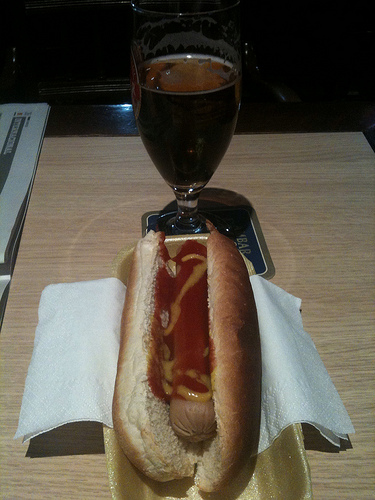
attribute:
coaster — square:
[135, 202, 274, 285]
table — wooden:
[276, 132, 363, 286]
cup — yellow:
[99, 245, 322, 498]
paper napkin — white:
[251, 275, 338, 441]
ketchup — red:
[144, 236, 219, 405]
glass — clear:
[123, 33, 206, 101]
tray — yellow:
[102, 234, 313, 498]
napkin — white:
[38, 290, 88, 425]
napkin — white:
[56, 274, 339, 432]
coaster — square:
[138, 198, 279, 284]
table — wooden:
[3, 123, 373, 499]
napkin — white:
[27, 275, 357, 455]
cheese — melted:
[156, 248, 209, 345]